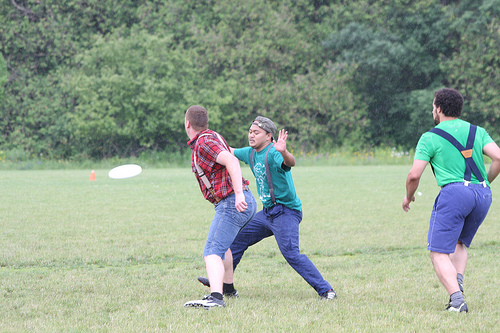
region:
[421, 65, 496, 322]
A big fat man running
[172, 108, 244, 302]
A big fat man running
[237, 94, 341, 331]
A big man running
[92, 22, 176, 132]
A thick green bush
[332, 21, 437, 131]
A thick green bush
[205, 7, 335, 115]
A thick green bush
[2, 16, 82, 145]
A thick green bush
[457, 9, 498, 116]
A thick green bush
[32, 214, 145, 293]
A thick green grass field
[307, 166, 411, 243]
A thick green grass field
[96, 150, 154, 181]
the disc is white in colour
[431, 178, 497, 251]
the short is blue in colour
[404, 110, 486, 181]
the shirt is green in colour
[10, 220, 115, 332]
the grass is green in colour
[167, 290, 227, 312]
the shoes are black and white in colour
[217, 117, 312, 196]
the hands are raised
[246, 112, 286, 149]
the cap is tilted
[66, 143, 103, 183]
the cone is white in colour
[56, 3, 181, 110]
the trees are green in colour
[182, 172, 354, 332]
the legs are apart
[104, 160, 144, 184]
The white frisbee in the air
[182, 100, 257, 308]
The man with the red plaid shirt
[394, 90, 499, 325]
The man in a green shirt and shorts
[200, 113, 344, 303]
The man in the green shirt and jeans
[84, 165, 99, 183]
The orange cone on the ground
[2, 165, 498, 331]
The large grass field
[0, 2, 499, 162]
The trees beyond the field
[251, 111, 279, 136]
The hat being worn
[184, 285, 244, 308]
The shoes of the man wearing the red shirt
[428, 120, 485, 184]
The suspenders with the brown patch on the back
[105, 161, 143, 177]
A white Frisbee being thrown.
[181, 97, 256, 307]
A man wearing a red plaid shirt.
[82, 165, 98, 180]
A orange cone in the grass.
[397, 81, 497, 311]
A man wearing a green shirt.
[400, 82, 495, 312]
A man wearing blue suspenders.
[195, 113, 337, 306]
A man wearing blue jeans.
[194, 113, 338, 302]
A man wearing a hat.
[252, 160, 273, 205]
A design on a shirt.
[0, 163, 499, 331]
A field of grass.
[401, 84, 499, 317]
A man wearing blue pants.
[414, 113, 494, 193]
man is wearing suspenders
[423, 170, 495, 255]
blue shorts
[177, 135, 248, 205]
red plaid shirt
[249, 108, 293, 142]
wearing baseball cap backwards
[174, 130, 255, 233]
tan suspenders on his pants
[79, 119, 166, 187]
frisbee is white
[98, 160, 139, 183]
frisbee is in the air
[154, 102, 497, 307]
three men playing frisbee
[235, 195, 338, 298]
man is wearing blue jeans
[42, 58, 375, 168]
trees behind the three men